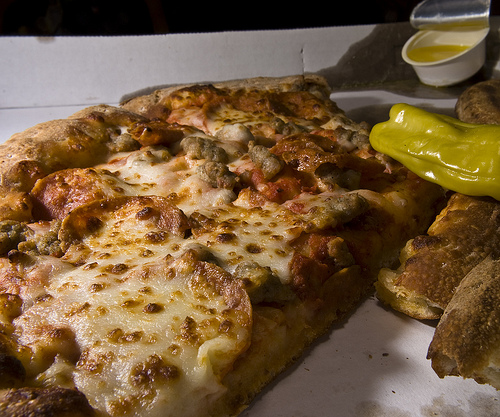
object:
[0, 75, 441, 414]
crust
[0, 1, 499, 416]
table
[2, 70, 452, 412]
pizza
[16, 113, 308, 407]
cheese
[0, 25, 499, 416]
box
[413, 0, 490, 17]
lid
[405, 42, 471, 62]
dipping sauce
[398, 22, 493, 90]
container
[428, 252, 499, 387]
crust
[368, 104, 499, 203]
banana pepper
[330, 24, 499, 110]
box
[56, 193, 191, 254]
pepperoni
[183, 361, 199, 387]
white gooey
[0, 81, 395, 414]
pizza top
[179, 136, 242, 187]
sausage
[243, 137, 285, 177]
sausage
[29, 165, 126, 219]
pepperoni